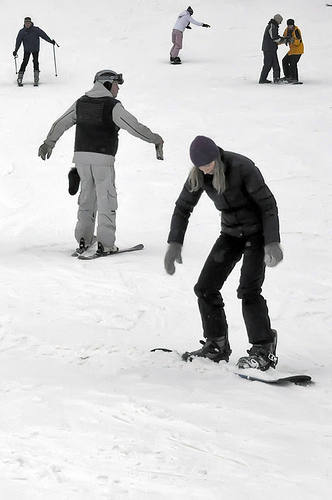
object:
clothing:
[163, 145, 285, 343]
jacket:
[279, 25, 304, 57]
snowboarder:
[167, 4, 211, 66]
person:
[166, 135, 283, 368]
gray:
[74, 150, 118, 247]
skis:
[77, 243, 145, 262]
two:
[12, 33, 61, 83]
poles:
[51, 41, 59, 79]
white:
[56, 427, 163, 489]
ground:
[0, 0, 332, 500]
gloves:
[37, 139, 55, 161]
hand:
[153, 135, 166, 161]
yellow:
[293, 43, 303, 54]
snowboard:
[149, 347, 313, 386]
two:
[257, 12, 305, 87]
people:
[36, 66, 166, 254]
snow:
[26, 352, 49, 397]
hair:
[212, 151, 227, 195]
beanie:
[189, 134, 220, 168]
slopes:
[105, 3, 161, 62]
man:
[255, 13, 286, 87]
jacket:
[166, 150, 282, 247]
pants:
[193, 232, 278, 349]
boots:
[235, 327, 279, 373]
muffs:
[103, 80, 113, 91]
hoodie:
[172, 4, 205, 32]